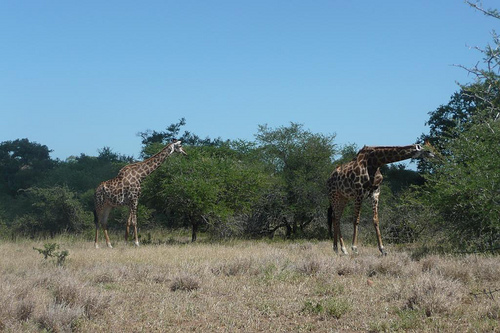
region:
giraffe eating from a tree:
[315, 127, 439, 265]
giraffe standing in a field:
[81, 134, 191, 248]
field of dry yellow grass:
[2, 228, 496, 331]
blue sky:
[1, 1, 499, 171]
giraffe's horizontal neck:
[371, 141, 414, 167]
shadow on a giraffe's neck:
[363, 148, 404, 177]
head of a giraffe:
[170, 134, 186, 159]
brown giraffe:
[84, 136, 201, 240]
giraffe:
[321, 123, 441, 255]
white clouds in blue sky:
[110, 31, 161, 68]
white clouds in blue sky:
[314, 39, 368, 89]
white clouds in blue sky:
[187, 38, 244, 73]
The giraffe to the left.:
[89, 140, 195, 251]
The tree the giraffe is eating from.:
[141, 139, 285, 239]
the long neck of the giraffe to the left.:
[134, 147, 179, 178]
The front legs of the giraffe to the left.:
[122, 202, 149, 243]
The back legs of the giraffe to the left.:
[88, 206, 125, 253]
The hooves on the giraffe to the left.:
[121, 232, 144, 252]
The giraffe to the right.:
[312, 130, 447, 253]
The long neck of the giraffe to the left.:
[375, 139, 416, 175]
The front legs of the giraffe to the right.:
[349, 192, 398, 264]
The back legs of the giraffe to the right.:
[323, 200, 350, 261]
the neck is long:
[130, 140, 170, 181]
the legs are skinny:
[91, 198, 142, 244]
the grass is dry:
[155, 236, 355, 321]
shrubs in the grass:
[176, 255, 341, 290]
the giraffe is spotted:
[334, 155, 394, 261]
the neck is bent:
[353, 141, 430, 174]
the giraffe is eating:
[358, 135, 458, 180]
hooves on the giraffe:
[93, 241, 143, 248]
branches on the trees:
[162, 128, 329, 217]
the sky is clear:
[25, 22, 432, 127]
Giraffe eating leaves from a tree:
[321, 138, 466, 257]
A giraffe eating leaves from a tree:
[91, 136, 195, 249]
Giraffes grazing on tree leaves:
[88, 134, 447, 255]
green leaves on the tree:
[238, 159, 283, 215]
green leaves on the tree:
[193, 170, 225, 203]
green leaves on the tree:
[447, 170, 480, 216]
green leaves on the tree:
[438, 125, 464, 172]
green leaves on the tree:
[66, 196, 86, 221]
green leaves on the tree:
[27, 147, 47, 176]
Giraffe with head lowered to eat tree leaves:
[323, 141, 443, 258]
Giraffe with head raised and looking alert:
[91, 136, 188, 250]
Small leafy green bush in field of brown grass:
[30, 240, 71, 265]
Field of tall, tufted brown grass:
[1, 235, 498, 330]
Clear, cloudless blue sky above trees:
[1, 0, 498, 170]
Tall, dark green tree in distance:
[2, 136, 55, 168]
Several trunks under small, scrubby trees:
[268, 213, 315, 239]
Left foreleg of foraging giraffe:
[370, 189, 388, 256]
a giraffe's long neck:
[123, 135, 187, 174]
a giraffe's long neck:
[354, 131, 441, 171]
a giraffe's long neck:
[141, 148, 170, 177]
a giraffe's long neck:
[371, 142, 416, 164]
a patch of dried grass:
[33, 284, 83, 323]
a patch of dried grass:
[93, 274, 126, 304]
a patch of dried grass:
[163, 270, 225, 308]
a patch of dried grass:
[267, 288, 300, 325]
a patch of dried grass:
[183, 248, 215, 270]